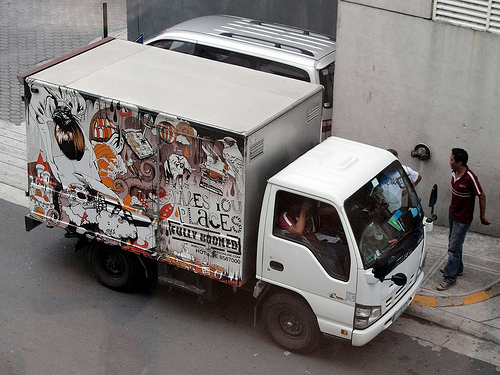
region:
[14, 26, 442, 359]
a truck on side the road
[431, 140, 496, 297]
a man wearing a red short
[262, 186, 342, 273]
a man inside a truck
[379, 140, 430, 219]
person stand on side of driver side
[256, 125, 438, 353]
cabin of truck is white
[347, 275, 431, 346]
a plate on white bumper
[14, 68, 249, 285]
a picture on side a van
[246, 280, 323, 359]
a front wheel of car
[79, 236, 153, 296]
back wheel of car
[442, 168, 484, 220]
red shirt with white stripe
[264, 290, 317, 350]
the tire of a truck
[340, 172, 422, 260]
the front window of a truck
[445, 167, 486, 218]
a man's shirt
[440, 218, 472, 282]
a man's jean pants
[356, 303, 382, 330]
a headlight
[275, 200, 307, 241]
the arm of a man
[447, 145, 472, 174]
the head of a man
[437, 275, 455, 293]
the shoe of a man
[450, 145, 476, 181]
Person has short hair.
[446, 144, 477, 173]
Person has dark hair.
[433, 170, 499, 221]
Person wearing maroon and white shirt.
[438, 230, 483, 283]
Person wearing blue jeans.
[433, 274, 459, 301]
Person wearing tennis shoes.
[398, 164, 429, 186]
Person wearing white shirt.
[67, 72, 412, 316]
White box truck near curb.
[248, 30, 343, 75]
Silver van near wall.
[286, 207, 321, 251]
Person wearing white and maroon shirt.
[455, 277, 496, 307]
Curb is painted yellow.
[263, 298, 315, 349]
it is the front tire of the truck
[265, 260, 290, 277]
is it the door handle on the truck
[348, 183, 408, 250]
the windshield of the truck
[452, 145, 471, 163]
the man has black hair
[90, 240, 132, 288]
is it the back tire of the white truck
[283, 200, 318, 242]
a person is sitting in the white truck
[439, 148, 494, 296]
there is a man standing outside of the white truck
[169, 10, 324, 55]
it is a white van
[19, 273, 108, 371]
the city street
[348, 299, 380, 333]
it is the front light of the white truck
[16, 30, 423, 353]
white delivery truck next to sidewalk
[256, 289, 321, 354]
front wheel of delivery truck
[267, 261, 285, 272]
door handle on delivery truck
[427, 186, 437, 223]
rearview mirror of delivery truck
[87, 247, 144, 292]
back tire of delivery truck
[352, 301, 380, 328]
front head lights of delivery truck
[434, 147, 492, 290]
man standing by delivery truck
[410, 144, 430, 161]
fire stand pipe in wall of building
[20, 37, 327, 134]
top roof of truck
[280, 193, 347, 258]
pasenger in delivery truck